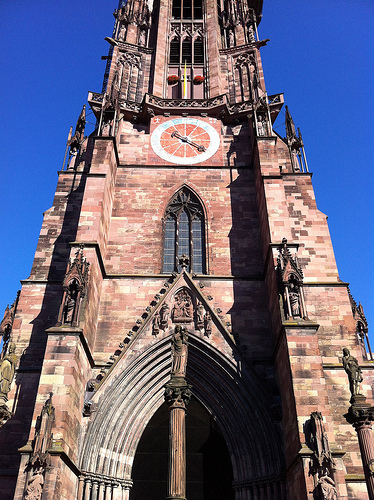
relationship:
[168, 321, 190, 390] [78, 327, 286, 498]
statue under arch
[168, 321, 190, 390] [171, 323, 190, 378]
statue of woman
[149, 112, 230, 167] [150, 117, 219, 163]
square around clock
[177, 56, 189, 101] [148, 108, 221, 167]
needle above clock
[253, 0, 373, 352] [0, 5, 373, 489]
sky to right of tower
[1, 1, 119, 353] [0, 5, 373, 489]
blue sky to left of tower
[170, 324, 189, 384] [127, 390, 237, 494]
statue above doorway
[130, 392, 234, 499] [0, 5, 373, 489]
arched doorway for tower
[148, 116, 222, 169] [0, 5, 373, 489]
clock on tower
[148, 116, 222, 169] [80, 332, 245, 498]
clock on door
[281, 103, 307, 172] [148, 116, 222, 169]
decorative spires to right of clock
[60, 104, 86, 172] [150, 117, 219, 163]
spires to left of clock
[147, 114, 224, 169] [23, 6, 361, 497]
clock on building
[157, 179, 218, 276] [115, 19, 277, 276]
window on building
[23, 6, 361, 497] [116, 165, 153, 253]
building made with bricks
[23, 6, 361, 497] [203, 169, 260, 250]
building made with bricks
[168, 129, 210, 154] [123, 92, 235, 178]
needle for clock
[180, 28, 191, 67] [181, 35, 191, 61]
window with grill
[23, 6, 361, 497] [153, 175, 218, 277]
building with window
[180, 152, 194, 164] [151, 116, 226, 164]
number on clock face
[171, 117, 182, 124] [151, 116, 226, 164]
number on clock face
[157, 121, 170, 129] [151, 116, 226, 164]
number on clock face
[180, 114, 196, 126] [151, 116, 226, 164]
number on clock face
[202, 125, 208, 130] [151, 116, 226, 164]
number on clock face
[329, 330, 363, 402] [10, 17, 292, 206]
statue on top of pillar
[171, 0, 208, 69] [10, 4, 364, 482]
tower of church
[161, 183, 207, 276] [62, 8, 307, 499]
window on church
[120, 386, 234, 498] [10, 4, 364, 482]
entrance of a church